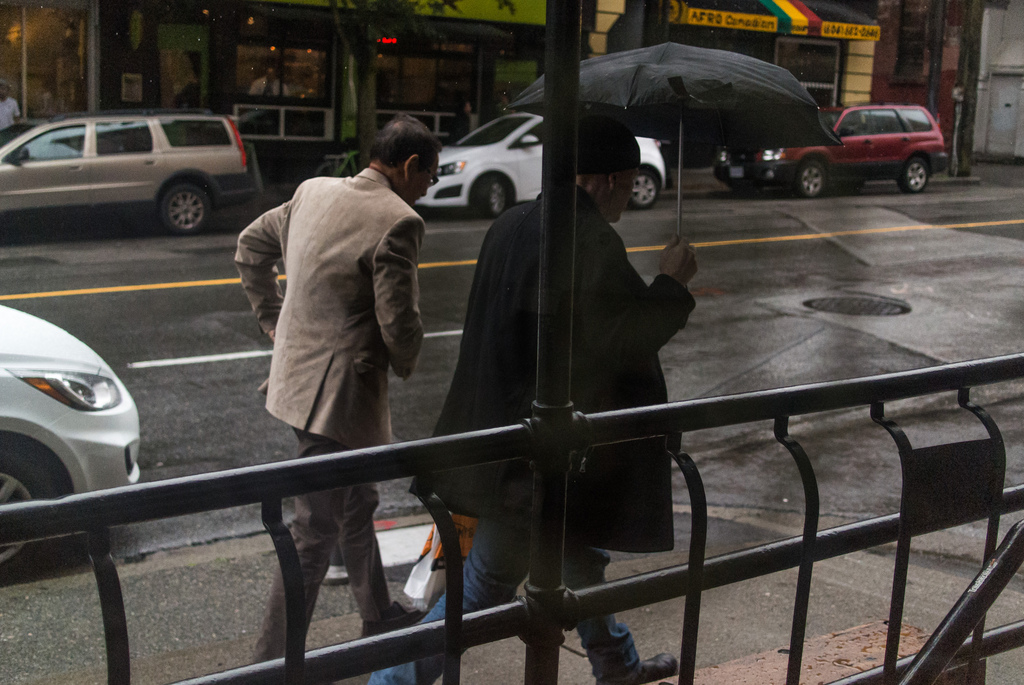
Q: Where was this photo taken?
A: On the sidewalk.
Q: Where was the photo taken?
A: On the city street.